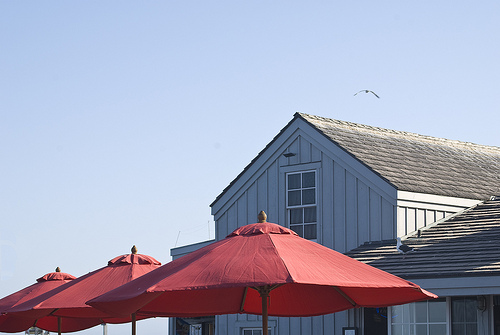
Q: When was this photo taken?
A: Today.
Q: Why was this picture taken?
A: For a magazine.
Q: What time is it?
A: Noon.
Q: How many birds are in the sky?
A: One.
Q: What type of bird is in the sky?
A: A seagull.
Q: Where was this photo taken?
A: Malibu.